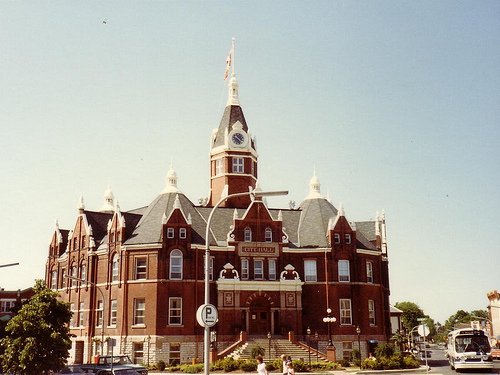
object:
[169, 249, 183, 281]
big window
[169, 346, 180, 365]
window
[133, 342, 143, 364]
window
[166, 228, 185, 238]
window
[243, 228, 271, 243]
window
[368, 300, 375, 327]
window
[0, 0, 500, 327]
sky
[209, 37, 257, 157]
clock tower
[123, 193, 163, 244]
roof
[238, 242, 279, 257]
sign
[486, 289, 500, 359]
building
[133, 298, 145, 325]
window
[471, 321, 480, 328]
sign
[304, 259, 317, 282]
window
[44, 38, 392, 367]
building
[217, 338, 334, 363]
stairs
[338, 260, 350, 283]
window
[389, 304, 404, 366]
building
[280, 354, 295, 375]
people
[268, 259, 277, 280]
window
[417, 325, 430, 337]
sign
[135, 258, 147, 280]
window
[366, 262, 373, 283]
window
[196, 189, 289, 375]
light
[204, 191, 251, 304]
pole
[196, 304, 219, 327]
sign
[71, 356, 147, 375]
truck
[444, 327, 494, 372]
bus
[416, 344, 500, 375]
road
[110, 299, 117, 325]
window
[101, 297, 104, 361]
pole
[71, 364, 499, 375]
road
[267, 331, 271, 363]
pole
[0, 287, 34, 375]
building